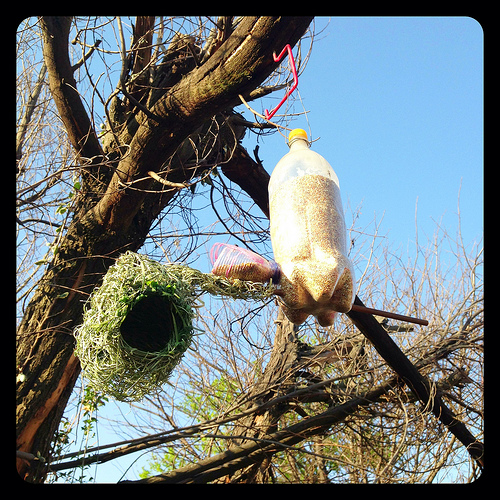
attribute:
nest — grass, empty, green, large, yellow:
[73, 250, 197, 404]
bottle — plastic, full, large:
[266, 129, 355, 327]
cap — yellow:
[285, 129, 308, 144]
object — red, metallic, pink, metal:
[261, 43, 301, 120]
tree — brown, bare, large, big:
[15, 13, 486, 486]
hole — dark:
[118, 290, 182, 356]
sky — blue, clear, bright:
[15, 16, 486, 485]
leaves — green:
[58, 177, 351, 483]